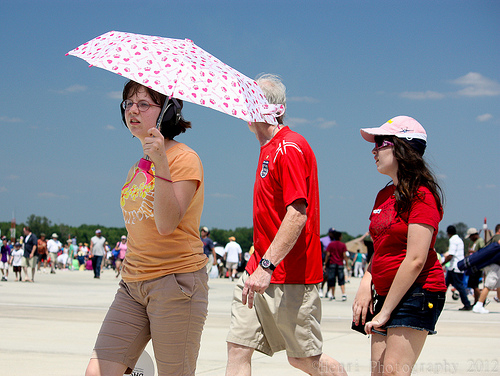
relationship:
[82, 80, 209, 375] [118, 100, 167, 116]
woman wearing glasses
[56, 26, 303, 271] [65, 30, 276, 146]
woman holding umbrella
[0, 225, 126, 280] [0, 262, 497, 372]
crowd on ground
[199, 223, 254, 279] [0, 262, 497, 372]
crowd on ground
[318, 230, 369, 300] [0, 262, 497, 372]
crowd on ground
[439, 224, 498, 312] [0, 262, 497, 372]
crowd on ground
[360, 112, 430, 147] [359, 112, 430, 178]
cap on head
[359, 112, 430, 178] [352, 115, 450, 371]
head of girl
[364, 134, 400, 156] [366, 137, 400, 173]
sunglasses on girl's face